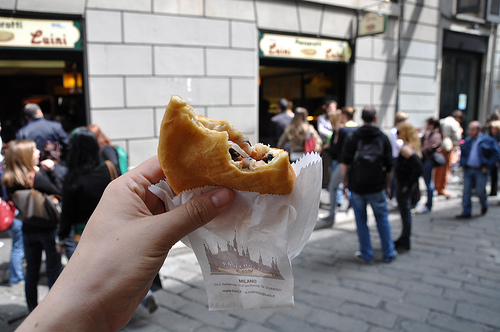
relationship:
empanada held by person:
[154, 94, 299, 222] [12, 160, 237, 330]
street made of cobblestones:
[131, 204, 500, 332] [132, 206, 499, 332]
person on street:
[61, 130, 121, 262] [131, 204, 500, 332]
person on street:
[459, 123, 495, 220] [131, 204, 500, 332]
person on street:
[434, 109, 463, 205] [131, 204, 500, 332]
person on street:
[419, 120, 445, 212] [131, 204, 500, 332]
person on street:
[326, 106, 361, 226] [131, 204, 500, 332]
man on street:
[339, 105, 400, 262] [131, 204, 500, 332]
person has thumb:
[12, 160, 237, 330] [146, 187, 238, 232]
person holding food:
[12, 160, 237, 330] [154, 94, 299, 222]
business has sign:
[258, 33, 350, 166] [357, 2, 389, 38]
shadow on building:
[376, 2, 425, 126] [2, 1, 500, 188]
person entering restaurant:
[326, 106, 361, 226] [258, 33, 350, 166]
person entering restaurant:
[269, 97, 297, 136] [258, 33, 350, 166]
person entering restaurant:
[278, 107, 322, 160] [258, 33, 350, 166]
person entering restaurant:
[419, 120, 445, 212] [258, 33, 350, 166]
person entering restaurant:
[15, 102, 66, 147] [0, 13, 84, 136]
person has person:
[12, 160, 237, 330] [11, 154, 237, 332]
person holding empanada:
[12, 160, 237, 330] [157, 94, 298, 195]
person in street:
[12, 160, 237, 330] [131, 204, 500, 332]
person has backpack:
[339, 105, 400, 262] [352, 136, 388, 172]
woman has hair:
[393, 123, 425, 255] [397, 121, 425, 158]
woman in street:
[393, 123, 425, 255] [131, 204, 500, 332]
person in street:
[339, 105, 400, 262] [131, 204, 500, 332]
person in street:
[459, 123, 495, 220] [131, 204, 500, 332]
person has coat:
[459, 123, 495, 220] [459, 136, 499, 169]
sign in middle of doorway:
[259, 32, 354, 65] [260, 30, 350, 212]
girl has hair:
[4, 139, 61, 306] [4, 139, 40, 192]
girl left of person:
[4, 139, 61, 306] [11, 154, 237, 332]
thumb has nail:
[146, 187, 238, 232] [211, 188, 233, 210]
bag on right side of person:
[303, 133, 316, 154] [278, 107, 322, 160]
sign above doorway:
[357, 2, 389, 38] [260, 30, 350, 212]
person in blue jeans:
[339, 105, 400, 262] [347, 184, 396, 264]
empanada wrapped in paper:
[157, 94, 298, 195] [149, 152, 324, 310]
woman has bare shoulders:
[393, 123, 425, 255] [400, 143, 425, 161]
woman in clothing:
[393, 123, 425, 255] [396, 153, 424, 240]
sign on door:
[458, 94, 468, 111] [443, 34, 491, 130]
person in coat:
[15, 102, 66, 147] [10, 117, 70, 160]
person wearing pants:
[434, 109, 463, 205] [435, 145, 452, 195]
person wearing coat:
[459, 123, 495, 220] [458, 136, 500, 169]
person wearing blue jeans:
[339, 105, 400, 262] [347, 184, 396, 264]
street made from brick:
[131, 204, 500, 332] [132, 206, 499, 332]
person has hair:
[61, 130, 121, 262] [64, 129, 102, 197]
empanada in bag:
[157, 94, 298, 195] [149, 152, 324, 310]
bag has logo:
[149, 152, 324, 310] [202, 231, 285, 300]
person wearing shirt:
[61, 130, 121, 262] [56, 162, 121, 236]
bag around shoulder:
[13, 170, 63, 223] [3, 170, 48, 192]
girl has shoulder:
[4, 139, 61, 306] [3, 170, 48, 192]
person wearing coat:
[15, 102, 66, 147] [10, 117, 70, 160]